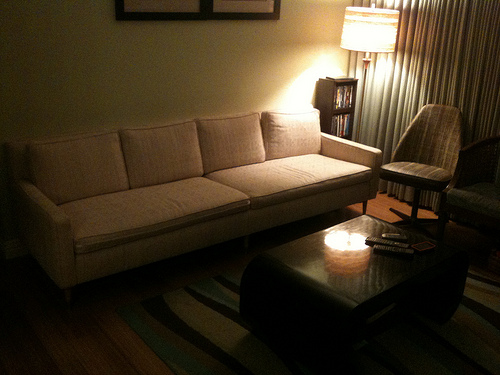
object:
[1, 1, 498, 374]
living room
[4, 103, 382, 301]
couch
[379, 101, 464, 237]
chair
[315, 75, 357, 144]
bookshelf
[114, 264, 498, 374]
rug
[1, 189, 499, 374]
floor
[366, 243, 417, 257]
remote controls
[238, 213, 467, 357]
coffee table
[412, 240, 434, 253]
tablet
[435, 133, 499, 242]
armchair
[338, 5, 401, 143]
floor lamp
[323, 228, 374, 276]
light reflection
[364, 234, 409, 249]
remote control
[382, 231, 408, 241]
remote control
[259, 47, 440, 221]
light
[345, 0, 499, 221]
curtains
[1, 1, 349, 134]
wall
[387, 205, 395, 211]
wheels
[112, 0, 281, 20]
picture frame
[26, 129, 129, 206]
cushion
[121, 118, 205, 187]
cushion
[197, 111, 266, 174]
cushion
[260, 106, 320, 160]
cushion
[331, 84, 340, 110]
dvds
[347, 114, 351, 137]
dvds